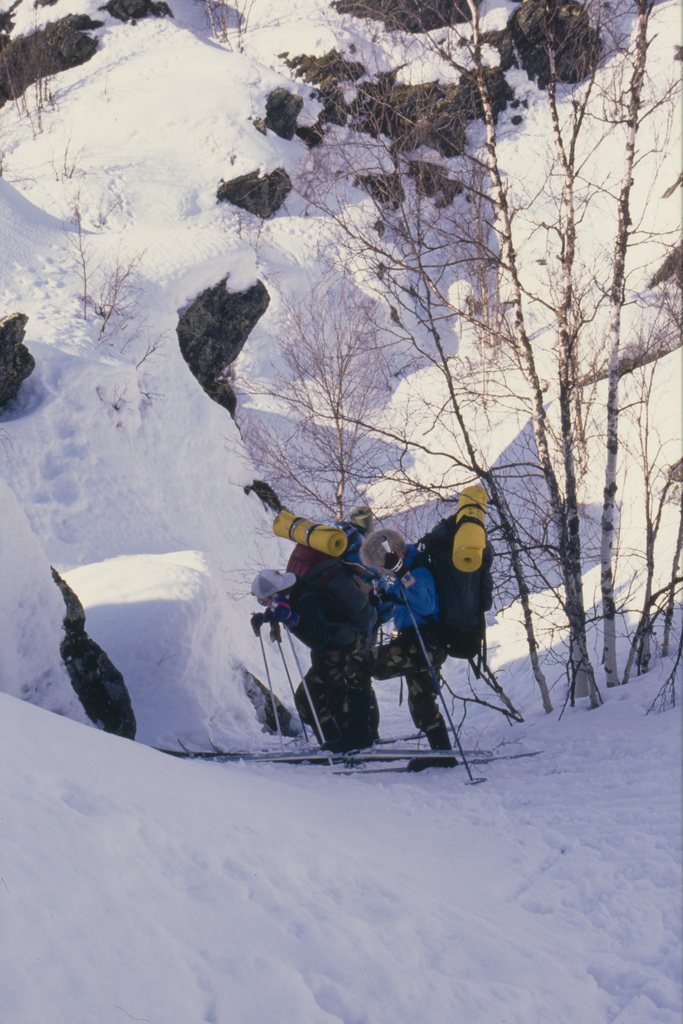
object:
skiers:
[253, 529, 494, 770]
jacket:
[376, 544, 442, 631]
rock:
[175, 273, 269, 420]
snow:
[0, 0, 683, 1024]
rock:
[50, 566, 137, 741]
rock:
[243, 670, 291, 738]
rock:
[0, 310, 36, 405]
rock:
[218, 167, 294, 217]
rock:
[0, 0, 683, 737]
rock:
[218, 41, 530, 221]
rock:
[459, 0, 602, 90]